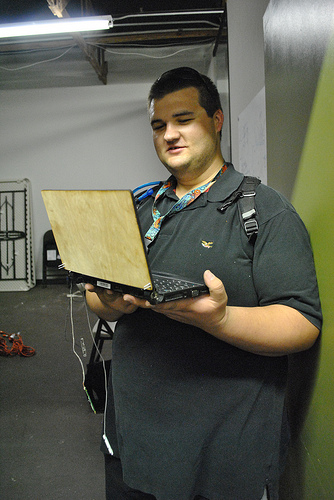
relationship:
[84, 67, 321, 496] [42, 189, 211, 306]
man with laptop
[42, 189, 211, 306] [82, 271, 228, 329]
laptop in hands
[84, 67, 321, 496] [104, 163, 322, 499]
man in shirt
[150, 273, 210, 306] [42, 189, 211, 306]
keyboard on laptop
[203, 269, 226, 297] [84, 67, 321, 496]
thumb on man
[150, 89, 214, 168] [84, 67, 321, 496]
face on man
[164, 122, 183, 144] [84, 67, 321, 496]
nose on man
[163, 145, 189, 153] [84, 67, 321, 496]
mouth on man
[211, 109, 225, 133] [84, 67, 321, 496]
ear of man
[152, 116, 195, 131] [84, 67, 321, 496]
eyes on man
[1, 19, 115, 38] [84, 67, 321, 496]
light over man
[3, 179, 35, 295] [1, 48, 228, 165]
table on wall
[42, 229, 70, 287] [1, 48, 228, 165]
chair on wall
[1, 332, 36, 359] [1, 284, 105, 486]
chord on ground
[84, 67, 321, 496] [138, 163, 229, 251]
man with lanyard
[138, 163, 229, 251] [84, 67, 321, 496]
lanyard on man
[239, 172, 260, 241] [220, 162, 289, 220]
strap on shoulder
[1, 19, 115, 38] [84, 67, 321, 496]
light above man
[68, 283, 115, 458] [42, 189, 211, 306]
chord from laptop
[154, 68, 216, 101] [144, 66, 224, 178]
sunglasses on head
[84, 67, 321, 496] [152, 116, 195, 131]
man with eyes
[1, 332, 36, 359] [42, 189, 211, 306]
chord from laptop